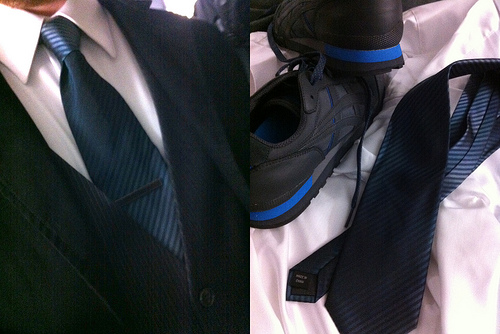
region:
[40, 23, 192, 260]
blue tie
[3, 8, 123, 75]
collar of white shirt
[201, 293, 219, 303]
button of coat on man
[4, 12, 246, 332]
black dress coat on man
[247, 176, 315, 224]
blue heel of black shoe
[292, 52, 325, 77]
black lace on shoe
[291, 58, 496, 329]
black tie laying on white cloth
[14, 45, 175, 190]
white shirt under blue tie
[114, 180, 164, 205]
black tie clip on blue tie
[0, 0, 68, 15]
neck and bottom chin of man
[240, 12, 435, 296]
Shoes next to a tie.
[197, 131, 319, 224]
Blue part of black shoes.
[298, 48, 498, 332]
Tie on the shirt.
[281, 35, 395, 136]
Laces on the shoes.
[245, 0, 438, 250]
A pair of black shoes.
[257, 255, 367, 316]
Tag on the tie.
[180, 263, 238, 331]
Button on the blazer.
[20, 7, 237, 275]
Tie on the man.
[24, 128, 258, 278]
Tie clip on the tie.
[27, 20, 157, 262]
Blue tie on the man.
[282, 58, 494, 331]
black tie on cloth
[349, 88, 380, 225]
black shoe lace on cloth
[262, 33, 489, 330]
white cloth with items on it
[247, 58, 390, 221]
black shoe on cloth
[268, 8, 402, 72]
black shoe on cloth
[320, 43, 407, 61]
blue heel of shoe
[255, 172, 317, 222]
blue heel of shoe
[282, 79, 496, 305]
back part of tie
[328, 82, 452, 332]
fabric is striped on tie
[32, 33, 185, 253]
blue tie on shirt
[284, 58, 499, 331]
tie laying on the bed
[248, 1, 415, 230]
black and blue shoes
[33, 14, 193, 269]
blue tie under the black jacket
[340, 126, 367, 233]
thin shoe string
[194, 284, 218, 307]
small button on the jacket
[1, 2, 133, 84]
white collar laying down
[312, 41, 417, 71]
blue stripe on the bottom of the shoe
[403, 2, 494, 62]
wrinkle in the fabric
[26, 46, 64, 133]
wrinkles on the shirt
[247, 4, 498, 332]
shoes laying next to a tie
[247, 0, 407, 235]
a pair of black and blue shoes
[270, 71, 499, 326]
a striped black and blue tie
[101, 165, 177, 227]
a black tie clip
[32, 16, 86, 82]
a knot tied in a tie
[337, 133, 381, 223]
a black shoe string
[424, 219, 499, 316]
a bright white shirt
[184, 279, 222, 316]
a button a suit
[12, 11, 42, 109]
a white collar on a shirt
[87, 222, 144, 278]
strips in a mans suit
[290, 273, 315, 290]
a tag on a tie